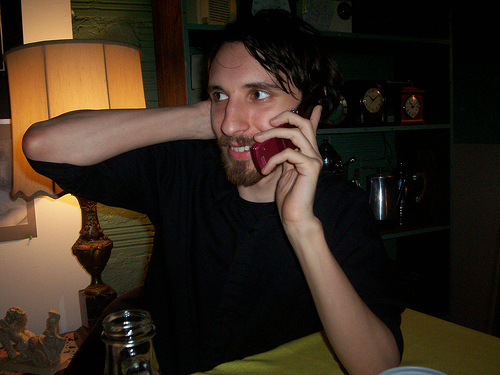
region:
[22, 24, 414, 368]
a man talking on a cellphone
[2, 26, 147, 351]
a lamp with orange lamp shade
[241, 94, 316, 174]
a red cellular flip phone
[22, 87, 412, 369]
a man's black shirt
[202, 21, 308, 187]
a man's bearded face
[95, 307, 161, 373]
a clear glass jar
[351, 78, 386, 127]
a clock on a shelf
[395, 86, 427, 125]
a clock on a shelf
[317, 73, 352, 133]
a clock on a shelf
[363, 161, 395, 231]
a silver metal pitcher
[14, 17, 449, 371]
the man on the cellphone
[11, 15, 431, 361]
the man is smiling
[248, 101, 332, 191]
the cellphone is red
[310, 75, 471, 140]
the clocks on the shelf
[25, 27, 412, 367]
the man is wearing a shirt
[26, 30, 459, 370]
the shirt is black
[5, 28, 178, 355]
The lamp behind the man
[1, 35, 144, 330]
the lamp is on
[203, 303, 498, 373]
the table cloth is green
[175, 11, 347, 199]
man talking on the phone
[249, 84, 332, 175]
the red cellphone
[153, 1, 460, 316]
brown and blue bookshelf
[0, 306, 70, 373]
small white statues on the side table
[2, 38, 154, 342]
brown and yellow lamp on the side table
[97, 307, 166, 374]
top of a glass bottle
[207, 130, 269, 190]
the man has a beard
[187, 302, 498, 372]
a yellow tablecloth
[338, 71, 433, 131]
clocks on the bookshelf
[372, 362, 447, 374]
part of a white dish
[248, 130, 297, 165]
the phone is orange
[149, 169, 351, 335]
the shirt is black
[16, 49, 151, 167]
the light is turned on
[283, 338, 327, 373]
the table clothe is green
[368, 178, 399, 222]
the jar is silver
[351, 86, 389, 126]
the clock is black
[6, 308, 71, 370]
the statue is white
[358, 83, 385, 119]
it is 10.10 on the clock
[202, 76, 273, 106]
his eyes are white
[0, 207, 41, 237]
a picture is on the wall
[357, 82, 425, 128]
two clocks on a shelf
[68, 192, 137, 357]
carved lamp base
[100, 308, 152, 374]
open glass jar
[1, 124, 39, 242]
picture pinned to the wall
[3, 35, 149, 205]
scalloped-edged lamp shade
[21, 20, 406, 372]
young man holding cell phone to his ear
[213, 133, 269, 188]
mustache and goatee on man's face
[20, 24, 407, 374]
man holding right hand against his ear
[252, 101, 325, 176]
fingers holding red cell phone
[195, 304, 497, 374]
yellow-green table cloth